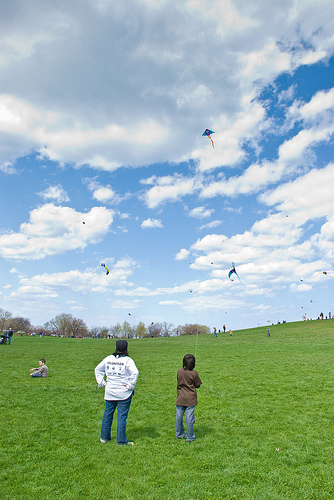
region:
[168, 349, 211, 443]
Child flying a kite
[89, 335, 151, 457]
Woman watching kites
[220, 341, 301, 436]
Long green grass on a hill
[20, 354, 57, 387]
Child sitting on grass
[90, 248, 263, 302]
Kites in a sky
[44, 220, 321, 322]
White clouds in a sky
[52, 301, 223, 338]
Brown trees by a hill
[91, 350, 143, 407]
White shirt on a woman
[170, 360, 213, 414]
Brown shirt on a child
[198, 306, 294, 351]
People walking on grass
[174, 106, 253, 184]
one blue and orange kite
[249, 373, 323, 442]
the grass is green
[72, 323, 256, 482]
the adult has a white shirt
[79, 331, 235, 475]
the child has a brown shirt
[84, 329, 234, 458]
they both wear jeans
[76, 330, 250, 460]
the activity is kite flying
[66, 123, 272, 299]
the clouds are white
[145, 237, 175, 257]
the sky is blue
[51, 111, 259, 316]
there are three kites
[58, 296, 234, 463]
there are two people flying a kite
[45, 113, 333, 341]
There are a bunch of kites in the sky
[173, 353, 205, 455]
Woman flying kite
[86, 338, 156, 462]
Woman wearing a white shirt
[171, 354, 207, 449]
Woman wearing a brown shirt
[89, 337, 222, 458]
Two women wearing jeans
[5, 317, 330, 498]
The grass is very green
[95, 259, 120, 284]
The kite is curved shaped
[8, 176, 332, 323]
There are clouds in the sky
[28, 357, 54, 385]
A boy is sitting in the grass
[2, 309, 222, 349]
There are trees in the distance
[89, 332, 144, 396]
Man with arms akimbo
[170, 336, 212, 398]
boy holding a string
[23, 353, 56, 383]
boy on the ground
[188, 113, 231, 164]
kite with a long yellow tail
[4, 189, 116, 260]
cumulous cloud floating by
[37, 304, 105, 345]
people at the tree line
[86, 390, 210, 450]
man and boy in blue jeans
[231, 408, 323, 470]
well tended grass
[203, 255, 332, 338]
crowd of people flying kites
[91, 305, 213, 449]
father and son together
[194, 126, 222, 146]
blue kite with red and yellow tail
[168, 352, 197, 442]
person wearing brown shirt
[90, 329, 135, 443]
person with white shirt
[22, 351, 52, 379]
boy sitting on grass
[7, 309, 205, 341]
trees on top of hill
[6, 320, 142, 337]
people in front of trees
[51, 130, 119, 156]
white clouds in sky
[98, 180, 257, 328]
blue cloudy sky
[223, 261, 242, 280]
blue and purple kite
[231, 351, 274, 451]
green grass on hillside